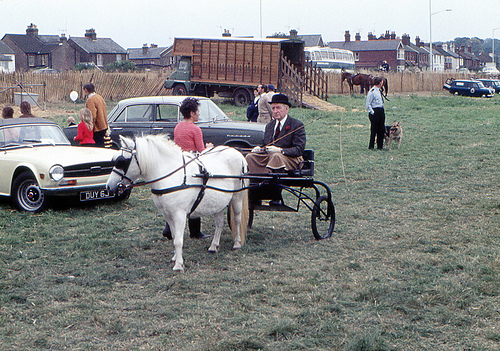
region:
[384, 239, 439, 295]
part of a ground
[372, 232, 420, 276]
part of a ground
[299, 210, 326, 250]
part of a wheel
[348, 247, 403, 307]
part of a field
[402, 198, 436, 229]
part of a ground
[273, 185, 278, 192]
part of a shoe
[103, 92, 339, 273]
Man riding a horse-drawn cart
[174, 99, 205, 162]
Woman talking to man in cart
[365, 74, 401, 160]
Man standing in field with dog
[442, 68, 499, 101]
Cars parked in front of the fence.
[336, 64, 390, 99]
Horses standing by the fence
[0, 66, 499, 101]
Fence at edge of field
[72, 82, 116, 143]
Man and girl walking from car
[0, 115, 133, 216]
Old white car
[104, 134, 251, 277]
White horse with blinders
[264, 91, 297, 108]
Top hat on man's head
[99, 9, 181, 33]
this is the sky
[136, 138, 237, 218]
this is a horse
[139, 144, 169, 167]
the horse is white in color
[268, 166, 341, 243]
this is a chart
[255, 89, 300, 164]
this is a man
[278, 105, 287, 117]
the man is light skinned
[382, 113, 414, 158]
this is a dog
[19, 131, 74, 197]
this is a vehicle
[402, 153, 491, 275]
this is a grass area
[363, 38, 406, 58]
this is a building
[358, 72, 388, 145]
this is a man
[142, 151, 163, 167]
the horse is white in color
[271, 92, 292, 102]
this is a hat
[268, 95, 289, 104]
the hat is black in color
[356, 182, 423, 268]
this is a grass area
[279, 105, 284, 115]
the man is light skinned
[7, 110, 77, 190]
this is a car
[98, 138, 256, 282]
a standing white horse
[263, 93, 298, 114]
black hat on a man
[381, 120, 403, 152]
a german shepred dog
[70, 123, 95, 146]
lady's red shirt she wearing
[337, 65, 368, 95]
a brown horse standing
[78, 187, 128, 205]
a plate on a car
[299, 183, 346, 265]
a wheel on a buggy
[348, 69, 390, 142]
a man looking back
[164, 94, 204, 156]
a lady with short hair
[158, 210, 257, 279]
legs on a white horse